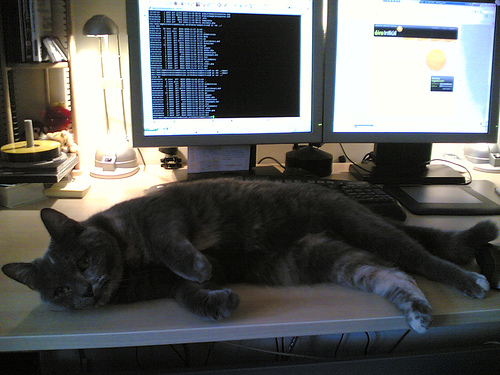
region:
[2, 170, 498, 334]
A cat laying on a computer table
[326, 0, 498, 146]
A A computer an open screen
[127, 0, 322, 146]
A computer screen with white lettering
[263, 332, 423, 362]
computer cables under the desk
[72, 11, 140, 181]
A lit desk top lamp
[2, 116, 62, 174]
computer discs on an open case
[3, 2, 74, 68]
books and cd's on a shelf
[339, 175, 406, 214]
Part of a black keyboard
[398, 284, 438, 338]
The paw of a cat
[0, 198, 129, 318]
A cat's face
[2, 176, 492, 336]
a reclining grey cat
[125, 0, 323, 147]
a computer screen with row of type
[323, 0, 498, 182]
a computer monitor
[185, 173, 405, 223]
a black keyboard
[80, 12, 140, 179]
a desk lamp turned on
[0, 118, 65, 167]
a spool of DVDs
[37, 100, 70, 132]
a red stuffed flower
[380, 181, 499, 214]
a grey and black mouse pad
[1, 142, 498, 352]
a white desktop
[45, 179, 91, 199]
a small pad of paper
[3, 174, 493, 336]
cat resting sideways on desk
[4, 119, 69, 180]
yellow discs on disc stand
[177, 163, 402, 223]
black keyboard behind cat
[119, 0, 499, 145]
two monitors next to each other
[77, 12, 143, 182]
silver lamp left of monitors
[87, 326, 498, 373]
electrical cords under desk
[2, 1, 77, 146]
white blinds cover window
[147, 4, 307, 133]
black background with blue letters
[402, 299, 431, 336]
one foot hanging off desk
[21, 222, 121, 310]
cat's head facing away from computers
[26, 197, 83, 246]
The left black ear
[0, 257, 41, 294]
the right black ear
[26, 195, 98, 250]
this is an ear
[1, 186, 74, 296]
these are black ears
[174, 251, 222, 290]
this is a paw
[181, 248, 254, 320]
these are the paws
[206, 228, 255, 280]
this is the belly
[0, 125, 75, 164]
these are yellow cds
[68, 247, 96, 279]
this is an eye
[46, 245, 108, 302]
these are the eyes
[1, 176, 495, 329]
a gray cat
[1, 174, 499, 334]
a cat lying down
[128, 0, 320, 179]
a computer monitor behind the cat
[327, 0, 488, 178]
a computer monitor behind the cat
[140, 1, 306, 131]
the screen of the computer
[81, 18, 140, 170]
a lamp on the table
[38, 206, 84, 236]
an ear on the cat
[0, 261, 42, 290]
an ear on the cat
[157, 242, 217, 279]
one of the cat's paws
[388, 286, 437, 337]
a cat's back foot